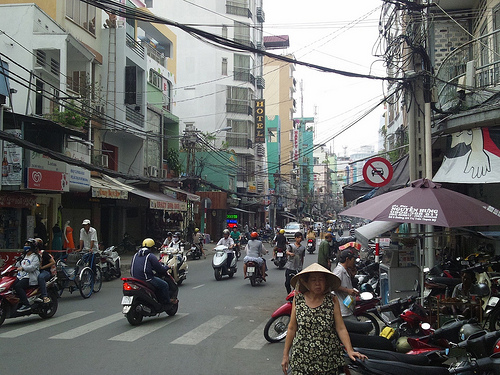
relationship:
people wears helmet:
[278, 261, 370, 375] [221, 227, 231, 234]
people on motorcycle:
[278, 261, 370, 375] [116, 269, 195, 331]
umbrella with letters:
[335, 174, 499, 231] [385, 200, 440, 225]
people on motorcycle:
[278, 261, 370, 375] [112, 230, 189, 326]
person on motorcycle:
[190, 226, 202, 245] [181, 240, 204, 260]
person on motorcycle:
[209, 222, 284, 279] [207, 220, 289, 295]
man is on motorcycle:
[131, 235, 178, 313] [119, 276, 188, 324]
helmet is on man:
[142, 235, 155, 249] [131, 235, 178, 313]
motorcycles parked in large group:
[262, 257, 498, 367] [315, 228, 482, 363]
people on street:
[278, 261, 370, 375] [0, 257, 285, 370]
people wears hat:
[9, 212, 368, 372] [288, 261, 342, 295]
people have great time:
[278, 261, 370, 375] [1, 198, 380, 347]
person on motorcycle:
[0, 239, 34, 310] [1, 262, 77, 320]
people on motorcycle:
[278, 261, 370, 375] [154, 245, 189, 280]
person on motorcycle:
[13, 238, 41, 314] [204, 242, 239, 277]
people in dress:
[278, 261, 370, 375] [285, 291, 338, 366]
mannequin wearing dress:
[56, 204, 111, 284] [60, 217, 114, 277]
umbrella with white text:
[339, 166, 478, 247] [376, 191, 432, 232]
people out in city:
[9, 212, 368, 372] [0, 0, 498, 373]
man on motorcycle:
[127, 235, 181, 307] [108, 268, 189, 323]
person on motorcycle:
[233, 234, 269, 291] [242, 250, 269, 288]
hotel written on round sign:
[249, 96, 267, 140] [360, 156, 394, 187]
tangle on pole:
[373, 4, 437, 104] [401, 2, 421, 182]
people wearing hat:
[278, 261, 370, 375] [288, 261, 342, 295]